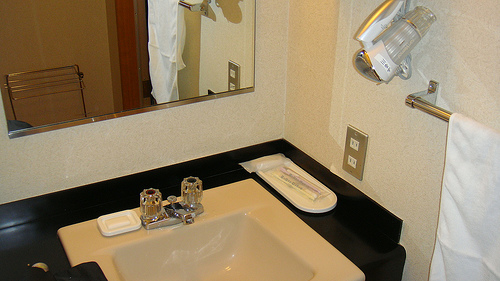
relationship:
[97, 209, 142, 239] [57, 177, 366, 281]
soap dish on sink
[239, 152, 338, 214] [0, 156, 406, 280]
toiletries on counter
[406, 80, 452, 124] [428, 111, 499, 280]
rack for towel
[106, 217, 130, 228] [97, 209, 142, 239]
soap on soap dish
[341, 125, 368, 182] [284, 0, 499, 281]
outlet on wall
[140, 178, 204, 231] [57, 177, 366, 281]
water fixture on sink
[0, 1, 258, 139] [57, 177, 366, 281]
mirror above sink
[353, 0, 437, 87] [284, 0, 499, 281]
hairdryer on wall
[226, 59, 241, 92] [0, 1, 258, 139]
outlet reflecting in mirror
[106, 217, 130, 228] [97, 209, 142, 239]
soap in soap dish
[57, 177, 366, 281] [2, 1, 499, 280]
sink in bathroom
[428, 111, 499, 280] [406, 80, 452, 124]
towel on rack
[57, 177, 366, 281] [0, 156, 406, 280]
sink and counter